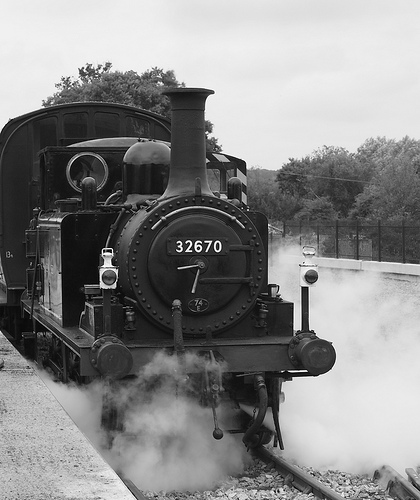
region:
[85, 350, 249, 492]
this is a lot of steam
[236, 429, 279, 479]
this is a track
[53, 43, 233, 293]
this is a train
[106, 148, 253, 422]
the train is black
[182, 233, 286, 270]
this is a number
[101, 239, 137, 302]
this is a light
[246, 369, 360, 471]
the train is made of steel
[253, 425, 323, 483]
the track is made of steel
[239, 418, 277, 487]
the track has rust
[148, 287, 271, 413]
the photo is black and white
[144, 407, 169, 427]
part of a smoke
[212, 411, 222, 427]
part of a metal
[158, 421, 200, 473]
part of a smoke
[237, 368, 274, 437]
part of a pipe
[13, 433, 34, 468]
part of a metal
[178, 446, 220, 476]
part of a smoke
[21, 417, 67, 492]
part of a rail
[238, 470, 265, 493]
part of a geound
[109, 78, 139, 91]
leaves on the tree.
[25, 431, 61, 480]
platform near the tracks.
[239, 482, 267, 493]
pebbles on the tracks.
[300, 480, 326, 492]
track made of steel.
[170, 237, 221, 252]
number on the train.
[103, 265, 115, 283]
headlight on the train.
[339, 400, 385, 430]
steam coming from the train.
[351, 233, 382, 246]
fence near the tracks.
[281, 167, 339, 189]
wire suspended in the air.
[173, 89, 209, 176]
smoke stack on the train.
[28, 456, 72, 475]
platform near the train.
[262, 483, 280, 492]
pebbles near the tracks.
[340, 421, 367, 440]
steam coming from the train.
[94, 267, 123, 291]
headlight on the train.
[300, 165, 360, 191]
wire in the air.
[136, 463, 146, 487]
THAT IS WHITE SMOKE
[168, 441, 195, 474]
THAT IS WHITE SMOKE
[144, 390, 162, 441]
THAT IS WHITE SMOKE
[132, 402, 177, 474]
THAT IS WHITE SMOKE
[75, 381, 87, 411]
THAT IS WHITE SMOKE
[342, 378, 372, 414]
THAT IS WHITE SMOKE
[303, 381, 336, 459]
THAT IS WHITE SMOKE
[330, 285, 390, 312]
THAT IS WHITE SMOKE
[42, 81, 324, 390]
THAT IS A TRAIN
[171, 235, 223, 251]
NUMBERS ON THE TRAIN